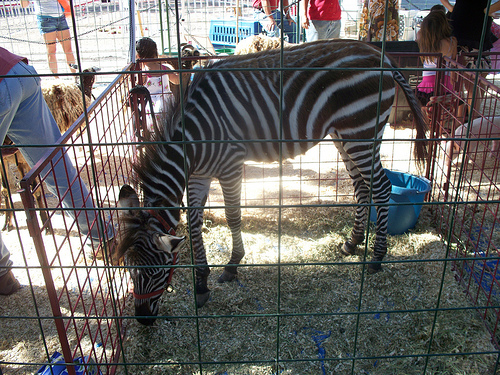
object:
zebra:
[88, 34, 442, 328]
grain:
[121, 195, 500, 373]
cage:
[0, 48, 500, 373]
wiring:
[1, 1, 499, 373]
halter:
[130, 201, 177, 301]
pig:
[439, 114, 500, 168]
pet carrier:
[206, 16, 264, 54]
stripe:
[185, 99, 244, 175]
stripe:
[314, 70, 388, 133]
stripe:
[249, 68, 288, 159]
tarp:
[309, 331, 334, 370]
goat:
[42, 63, 101, 132]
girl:
[402, 5, 467, 111]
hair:
[413, 4, 453, 63]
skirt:
[417, 76, 450, 96]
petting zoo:
[0, 1, 500, 373]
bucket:
[361, 169, 431, 235]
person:
[0, 47, 125, 299]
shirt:
[0, 47, 28, 82]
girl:
[126, 36, 196, 138]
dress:
[145, 66, 178, 134]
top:
[449, 1, 497, 50]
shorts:
[449, 47, 500, 71]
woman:
[23, 0, 77, 81]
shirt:
[33, 0, 65, 18]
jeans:
[0, 63, 116, 276]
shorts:
[36, 15, 72, 33]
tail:
[391, 66, 433, 170]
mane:
[126, 69, 195, 187]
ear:
[116, 183, 141, 214]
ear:
[157, 232, 189, 255]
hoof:
[196, 292, 211, 309]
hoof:
[218, 269, 238, 284]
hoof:
[341, 243, 352, 256]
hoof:
[364, 265, 386, 279]